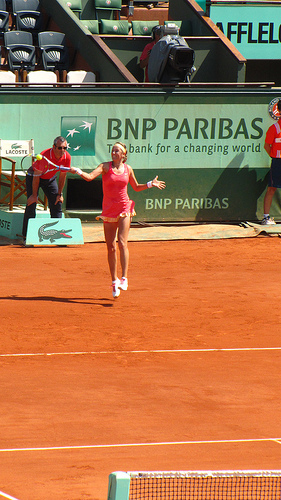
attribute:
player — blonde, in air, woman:
[52, 139, 149, 298]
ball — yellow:
[27, 142, 49, 168]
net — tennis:
[129, 453, 280, 500]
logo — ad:
[27, 95, 274, 186]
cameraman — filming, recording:
[132, 7, 212, 93]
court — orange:
[13, 241, 280, 492]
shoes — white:
[113, 276, 131, 299]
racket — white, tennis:
[21, 153, 86, 182]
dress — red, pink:
[100, 141, 126, 224]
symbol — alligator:
[1, 130, 26, 176]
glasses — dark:
[55, 145, 69, 159]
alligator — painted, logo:
[20, 211, 88, 257]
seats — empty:
[77, 1, 203, 33]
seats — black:
[2, 16, 77, 68]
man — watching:
[31, 130, 70, 227]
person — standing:
[244, 88, 279, 214]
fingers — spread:
[136, 179, 171, 190]